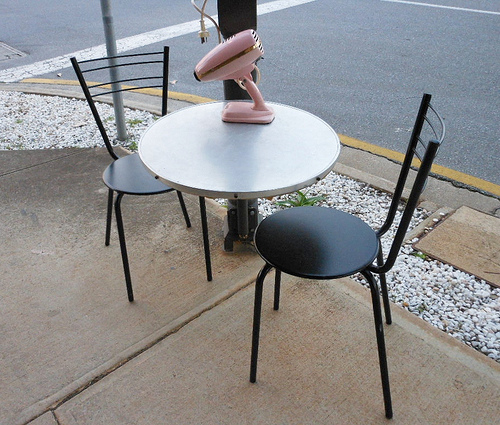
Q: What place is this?
A: It is a sidewalk.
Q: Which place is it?
A: It is a sidewalk.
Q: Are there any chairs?
A: Yes, there is a chair.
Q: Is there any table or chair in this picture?
A: Yes, there is a chair.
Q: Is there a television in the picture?
A: No, there are no televisions.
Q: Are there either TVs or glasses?
A: No, there are no TVs or glasses.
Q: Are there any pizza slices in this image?
A: No, there are no pizza slices.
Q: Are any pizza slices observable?
A: No, there are no pizza slices.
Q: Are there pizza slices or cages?
A: No, there are no pizza slices or cages.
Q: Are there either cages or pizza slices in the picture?
A: No, there are no pizza slices or cages.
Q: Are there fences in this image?
A: No, there are no fences.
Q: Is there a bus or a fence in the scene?
A: No, there are no fences or buses.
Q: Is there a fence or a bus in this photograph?
A: No, there are no fences or buses.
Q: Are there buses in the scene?
A: No, there are no buses.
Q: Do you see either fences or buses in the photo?
A: No, there are no buses or fences.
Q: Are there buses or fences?
A: No, there are no buses or fences.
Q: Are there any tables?
A: Yes, there is a table.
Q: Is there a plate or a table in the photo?
A: Yes, there is a table.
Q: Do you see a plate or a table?
A: Yes, there is a table.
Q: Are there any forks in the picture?
A: No, there are no forks.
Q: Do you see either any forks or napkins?
A: No, there are no forks or napkins.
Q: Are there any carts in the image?
A: No, there are no carts.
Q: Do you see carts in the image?
A: No, there are no carts.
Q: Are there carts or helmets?
A: No, there are no carts or helmets.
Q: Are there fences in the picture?
A: No, there are no fences.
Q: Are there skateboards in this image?
A: No, there are no skateboards.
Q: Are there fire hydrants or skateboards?
A: No, there are no skateboards or fire hydrants.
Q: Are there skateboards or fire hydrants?
A: No, there are no skateboards or fire hydrants.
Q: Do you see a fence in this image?
A: No, there are no fences.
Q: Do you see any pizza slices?
A: No, there are no pizza slices.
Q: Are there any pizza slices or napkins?
A: No, there are no pizza slices or napkins.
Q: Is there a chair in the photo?
A: Yes, there is a chair.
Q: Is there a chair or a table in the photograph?
A: Yes, there is a chair.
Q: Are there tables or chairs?
A: Yes, there is a chair.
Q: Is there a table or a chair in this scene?
A: Yes, there is a chair.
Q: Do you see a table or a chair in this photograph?
A: Yes, there is a chair.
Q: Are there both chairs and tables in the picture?
A: Yes, there are both a chair and a table.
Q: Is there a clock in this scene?
A: No, there are no clocks.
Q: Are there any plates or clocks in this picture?
A: No, there are no clocks or plates.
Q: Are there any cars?
A: No, there are no cars.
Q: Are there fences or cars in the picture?
A: No, there are no cars or fences.